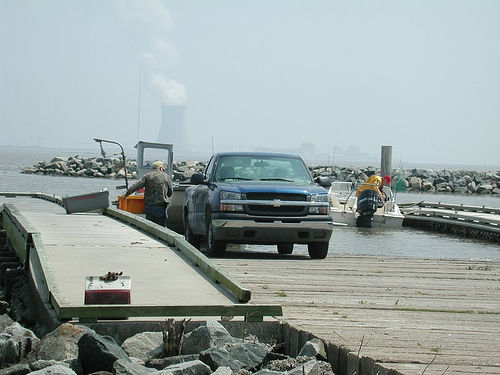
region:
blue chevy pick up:
[180, 148, 339, 260]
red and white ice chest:
[82, 273, 132, 321]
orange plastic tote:
[115, 192, 148, 215]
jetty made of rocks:
[18, 144, 496, 199]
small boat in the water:
[327, 175, 408, 235]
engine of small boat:
[356, 188, 378, 231]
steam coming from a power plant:
[133, 50, 192, 108]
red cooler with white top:
[83, 273, 131, 318]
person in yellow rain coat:
[355, 173, 384, 225]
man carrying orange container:
[117, 159, 173, 227]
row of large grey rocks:
[20, 152, 498, 194]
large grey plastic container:
[62, 189, 109, 214]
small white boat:
[326, 180, 406, 227]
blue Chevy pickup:
[185, 150, 334, 259]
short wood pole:
[380, 144, 393, 189]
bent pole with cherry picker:
[97, 138, 128, 188]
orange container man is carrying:
[118, 193, 145, 213]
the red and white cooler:
[83, 275, 132, 315]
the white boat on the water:
[327, 177, 405, 227]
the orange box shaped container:
[118, 193, 148, 215]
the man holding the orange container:
[118, 161, 172, 225]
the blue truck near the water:
[182, 151, 334, 261]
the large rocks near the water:
[1, 154, 498, 372]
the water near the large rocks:
[2, 148, 499, 257]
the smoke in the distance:
[108, 0, 187, 106]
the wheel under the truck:
[205, 218, 227, 256]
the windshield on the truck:
[213, 154, 313, 183]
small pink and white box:
[78, 265, 134, 305]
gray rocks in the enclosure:
[202, 327, 281, 360]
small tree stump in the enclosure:
[158, 317, 191, 354]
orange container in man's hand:
[108, 188, 158, 213]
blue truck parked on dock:
[179, 141, 339, 253]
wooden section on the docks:
[293, 264, 484, 307]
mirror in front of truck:
[248, 152, 280, 169]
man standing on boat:
[353, 166, 404, 231]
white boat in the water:
[321, 163, 410, 235]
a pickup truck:
[181, 148, 336, 265]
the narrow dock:
[398, 195, 499, 233]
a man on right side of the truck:
[119, 157, 174, 226]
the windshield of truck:
[211, 152, 313, 182]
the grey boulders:
[0, 151, 497, 373]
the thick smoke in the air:
[118, 3, 189, 106]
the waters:
[0, 155, 499, 261]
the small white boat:
[329, 173, 406, 229]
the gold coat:
[353, 172, 384, 209]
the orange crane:
[113, 187, 145, 212]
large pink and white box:
[72, 263, 141, 305]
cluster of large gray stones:
[48, 326, 223, 369]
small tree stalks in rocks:
[153, 315, 199, 360]